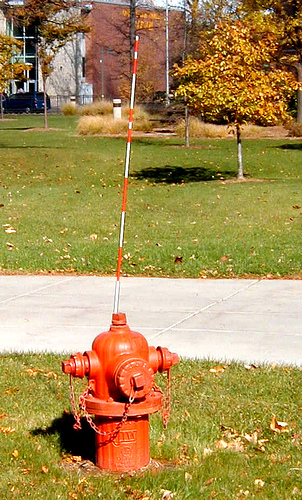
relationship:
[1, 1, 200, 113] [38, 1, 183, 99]
building with walls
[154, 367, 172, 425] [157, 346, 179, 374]
chain on cap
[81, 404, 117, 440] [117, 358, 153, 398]
chain on cap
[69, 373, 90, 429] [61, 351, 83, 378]
chain on cap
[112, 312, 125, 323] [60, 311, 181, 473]
top screw on hydrant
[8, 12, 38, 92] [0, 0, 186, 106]
windows of building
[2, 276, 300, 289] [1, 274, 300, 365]
edge of sidewalk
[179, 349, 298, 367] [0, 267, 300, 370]
edge of sidewalk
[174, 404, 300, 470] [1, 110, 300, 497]
dry leaves on ground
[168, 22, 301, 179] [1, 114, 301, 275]
tree growing on lawn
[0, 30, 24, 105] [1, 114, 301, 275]
tree growing on lawn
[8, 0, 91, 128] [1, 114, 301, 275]
tree growing on lawn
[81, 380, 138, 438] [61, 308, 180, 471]
chain attached to fire hydrant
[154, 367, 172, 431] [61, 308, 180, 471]
chain attached to fire hydrant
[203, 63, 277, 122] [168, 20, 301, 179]
leaves on tree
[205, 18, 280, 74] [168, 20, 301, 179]
leaves on tree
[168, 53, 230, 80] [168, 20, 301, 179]
leaves on tree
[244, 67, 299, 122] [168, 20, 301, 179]
leaves on tree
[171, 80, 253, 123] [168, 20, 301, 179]
leaves on tree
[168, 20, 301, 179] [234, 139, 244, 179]
tree has tree trunk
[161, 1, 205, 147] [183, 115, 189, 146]
tree has tree trunk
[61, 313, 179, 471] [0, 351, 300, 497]
fire hydrant on grass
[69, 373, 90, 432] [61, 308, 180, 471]
chain attached to fire hydrant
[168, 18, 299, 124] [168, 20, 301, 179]
colorful foliage on tree